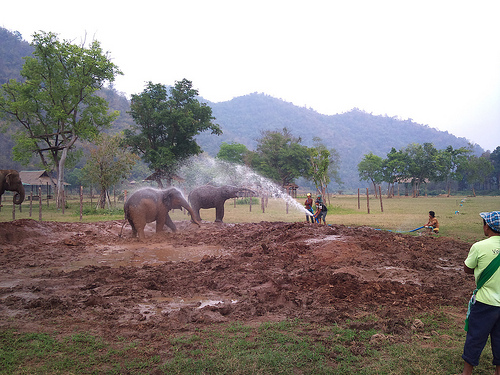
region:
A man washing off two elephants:
[99, 165, 342, 248]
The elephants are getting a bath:
[124, 160, 256, 240]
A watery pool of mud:
[88, 240, 218, 270]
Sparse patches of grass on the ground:
[217, 330, 310, 373]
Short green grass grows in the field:
[394, 196, 452, 208]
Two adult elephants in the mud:
[122, 174, 235, 233]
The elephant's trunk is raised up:
[237, 183, 258, 202]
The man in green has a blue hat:
[478, 205, 498, 230]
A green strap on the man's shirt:
[471, 248, 498, 291]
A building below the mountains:
[22, 168, 74, 200]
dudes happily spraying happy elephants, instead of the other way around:
[111, 150, 443, 243]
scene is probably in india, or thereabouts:
[0, 8, 499, 373]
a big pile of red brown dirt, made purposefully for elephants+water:
[1, 213, 482, 349]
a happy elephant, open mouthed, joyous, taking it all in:
[186, 178, 267, 227]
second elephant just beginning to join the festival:
[110, 183, 204, 245]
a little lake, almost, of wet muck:
[31, 239, 239, 283]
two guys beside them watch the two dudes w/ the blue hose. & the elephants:
[296, 188, 443, 237]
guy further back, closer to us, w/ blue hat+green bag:
[453, 205, 498, 373]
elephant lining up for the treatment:
[0, 166, 30, 221]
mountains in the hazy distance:
[0, 24, 488, 201]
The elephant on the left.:
[119, 186, 204, 231]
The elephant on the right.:
[182, 175, 259, 225]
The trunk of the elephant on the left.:
[176, 198, 204, 225]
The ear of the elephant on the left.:
[165, 188, 172, 208]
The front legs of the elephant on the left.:
[160, 208, 172, 231]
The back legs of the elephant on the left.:
[125, 219, 148, 240]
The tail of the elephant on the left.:
[112, 206, 131, 235]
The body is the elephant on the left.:
[125, 187, 163, 222]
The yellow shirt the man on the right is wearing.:
[465, 244, 499, 311]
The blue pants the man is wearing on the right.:
[457, 300, 497, 362]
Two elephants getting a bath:
[118, 168, 266, 249]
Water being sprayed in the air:
[185, 148, 311, 211]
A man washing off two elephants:
[310, 195, 336, 222]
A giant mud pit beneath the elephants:
[5, 214, 447, 334]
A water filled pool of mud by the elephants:
[90, 238, 216, 269]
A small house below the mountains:
[18, 166, 70, 201]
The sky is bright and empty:
[137, 3, 410, 77]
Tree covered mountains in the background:
[207, 88, 447, 155]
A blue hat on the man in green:
[478, 205, 498, 229]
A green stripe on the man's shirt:
[477, 255, 499, 295]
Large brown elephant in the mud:
[112, 173, 200, 253]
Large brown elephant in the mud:
[183, 170, 259, 231]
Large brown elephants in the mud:
[118, 164, 270, 236]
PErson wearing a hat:
[292, 185, 314, 226]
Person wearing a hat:
[311, 191, 333, 221]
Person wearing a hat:
[458, 170, 494, 322]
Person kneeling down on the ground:
[413, 205, 453, 247]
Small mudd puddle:
[134, 275, 245, 323]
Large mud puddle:
[82, 230, 244, 279]